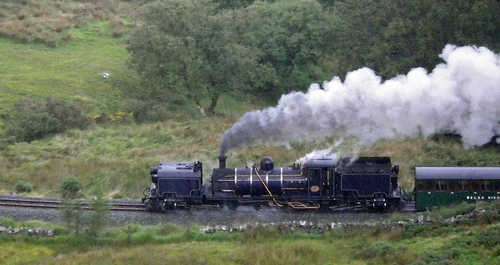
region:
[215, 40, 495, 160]
white steam exiting black train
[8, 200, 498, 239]
rock fence running the length of the tracks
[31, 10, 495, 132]
row of green trees in background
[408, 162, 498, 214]
green passenger car of train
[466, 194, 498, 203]
white letters on side of green train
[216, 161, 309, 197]
barrel of train is banded by gold banding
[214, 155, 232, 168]
stack where steam escapes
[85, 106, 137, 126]
yellow flowers in valley of pasture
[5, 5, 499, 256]
green pasture fields that railway has spliced through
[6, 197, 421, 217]
gravel surrounding metal train tracks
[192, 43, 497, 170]
smoke coming from a train's smoke stack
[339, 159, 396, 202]
the coal bin on a train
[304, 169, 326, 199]
a door on a train engine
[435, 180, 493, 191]
windows on a train car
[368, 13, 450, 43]
trees with leaves on them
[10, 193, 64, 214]
railroad track with gravel on both sides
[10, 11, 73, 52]
tall grass beside and area of short grass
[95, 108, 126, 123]
a cluster of yellow flowers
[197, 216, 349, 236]
rocks next to a traveling train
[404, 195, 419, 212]
stairs on a train car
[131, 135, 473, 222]
Train is black color.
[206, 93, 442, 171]
Smoke is coming out of engine.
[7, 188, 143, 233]
Track is brown color.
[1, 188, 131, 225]
Gravel is grey color.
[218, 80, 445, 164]
Smoke is grey color.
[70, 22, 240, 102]
Trees are green color.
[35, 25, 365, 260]
trees are on both sides of the track.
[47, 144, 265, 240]
Train is on track.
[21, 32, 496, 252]
Day time picture.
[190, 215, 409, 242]
Rocks are grey color.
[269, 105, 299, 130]
part of a smoke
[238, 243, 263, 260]
part of a grass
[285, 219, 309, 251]
part of a ground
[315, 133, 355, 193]
part of a smoke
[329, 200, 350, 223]
edge of a rail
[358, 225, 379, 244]
part of a ground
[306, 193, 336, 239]
part of a train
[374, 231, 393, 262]
part of a ground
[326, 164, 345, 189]
part of a train